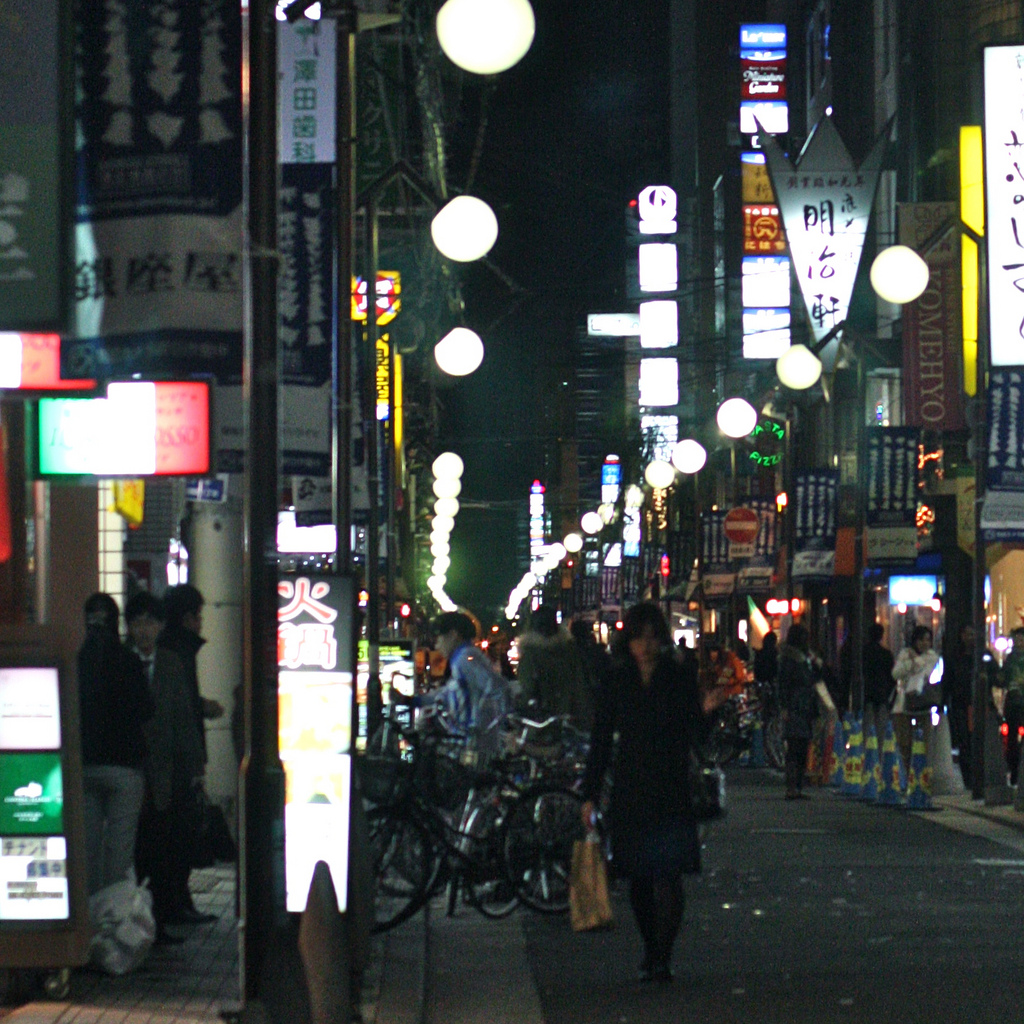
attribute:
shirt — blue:
[428, 656, 532, 801]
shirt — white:
[890, 648, 955, 707]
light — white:
[402, 5, 610, 120]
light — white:
[419, 173, 506, 275]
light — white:
[421, 318, 504, 399]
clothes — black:
[584, 569, 792, 997]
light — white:
[774, 323, 827, 423]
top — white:
[884, 636, 947, 701]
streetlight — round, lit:
[424, 189, 502, 267]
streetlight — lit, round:
[430, 1, 539, 75]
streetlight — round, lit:
[431, 323, 484, 380]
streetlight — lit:
[716, 395, 769, 441]